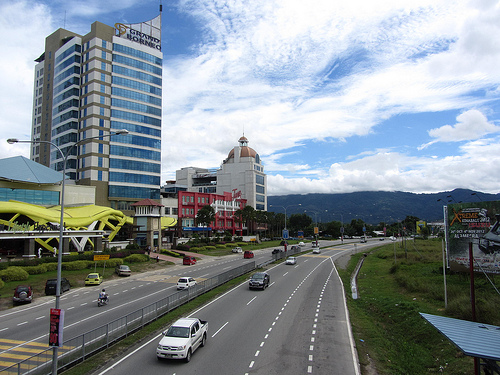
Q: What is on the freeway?
A: Vehicles.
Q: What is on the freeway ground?
A: White lines.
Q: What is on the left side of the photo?
A: Buildings.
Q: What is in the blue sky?
A: Clouds.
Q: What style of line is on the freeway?
A: Dotted line.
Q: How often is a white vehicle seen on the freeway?
A: Two times.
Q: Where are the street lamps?
A: On the left of the screen in the foreground.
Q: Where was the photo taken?
A: Over a highway.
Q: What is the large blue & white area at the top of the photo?
A: The sky.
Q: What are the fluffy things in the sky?
A: Clouds.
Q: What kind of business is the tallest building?
A: A hotel.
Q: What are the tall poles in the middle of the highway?
A: Street lights.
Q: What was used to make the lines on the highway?
A: Paint.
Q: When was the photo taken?
A: Daytime.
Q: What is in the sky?
A: Clouds.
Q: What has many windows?
A: Building.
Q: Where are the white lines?
A: Street.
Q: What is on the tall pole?
A: Lights.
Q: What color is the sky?
A: Blue.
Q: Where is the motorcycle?
A: Street.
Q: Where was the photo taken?
A: On the street.